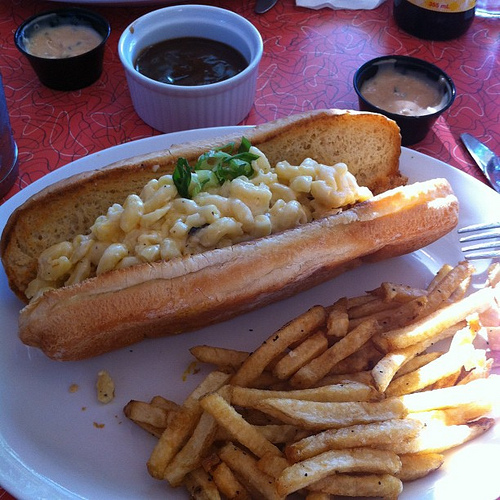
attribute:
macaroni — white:
[25, 145, 374, 298]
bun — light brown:
[1, 108, 459, 361]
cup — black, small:
[15, 10, 111, 91]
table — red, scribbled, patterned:
[2, 0, 500, 207]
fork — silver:
[457, 220, 499, 261]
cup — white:
[117, 4, 263, 133]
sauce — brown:
[132, 36, 250, 87]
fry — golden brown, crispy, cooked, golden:
[225, 304, 328, 387]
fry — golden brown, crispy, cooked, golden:
[273, 330, 329, 379]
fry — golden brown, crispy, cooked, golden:
[288, 315, 382, 390]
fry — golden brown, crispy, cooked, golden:
[326, 296, 349, 337]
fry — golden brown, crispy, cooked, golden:
[371, 285, 495, 353]